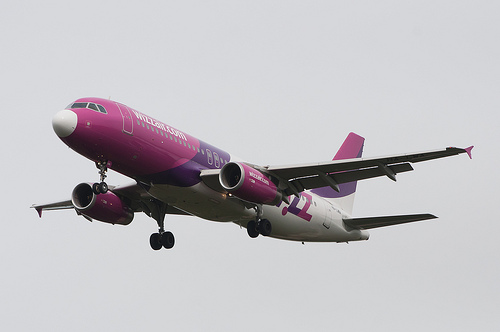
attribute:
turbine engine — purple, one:
[218, 160, 284, 207]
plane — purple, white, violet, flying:
[29, 95, 474, 251]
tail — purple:
[331, 131, 367, 161]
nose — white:
[52, 110, 80, 138]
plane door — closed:
[116, 101, 135, 136]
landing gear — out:
[94, 163, 272, 251]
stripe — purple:
[151, 142, 230, 187]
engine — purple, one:
[71, 182, 135, 227]